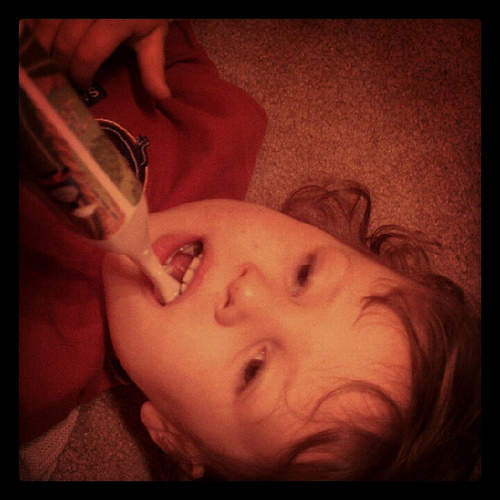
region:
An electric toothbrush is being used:
[20, 49, 182, 309]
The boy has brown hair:
[208, 185, 493, 477]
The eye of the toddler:
[222, 340, 284, 407]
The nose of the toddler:
[211, 259, 267, 330]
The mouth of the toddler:
[123, 230, 220, 311]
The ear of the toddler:
[137, 394, 207, 481]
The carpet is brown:
[260, 54, 472, 211]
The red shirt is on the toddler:
[20, 19, 268, 443]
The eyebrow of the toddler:
[323, 244, 370, 314]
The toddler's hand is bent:
[20, 18, 177, 104]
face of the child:
[98, 195, 447, 479]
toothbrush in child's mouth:
[13, 19, 183, 305]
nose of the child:
[216, 262, 281, 329]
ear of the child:
[140, 400, 206, 477]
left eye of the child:
[229, 338, 276, 398]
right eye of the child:
[288, 244, 326, 297]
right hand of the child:
[25, 17, 177, 99]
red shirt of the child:
[11, 13, 268, 435]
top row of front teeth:
[180, 253, 202, 291]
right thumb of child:
[135, 25, 170, 105]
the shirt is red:
[90, 55, 251, 222]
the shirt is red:
[26, 218, 175, 464]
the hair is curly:
[279, 165, 476, 351]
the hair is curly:
[252, 171, 424, 304]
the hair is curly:
[301, 178, 453, 459]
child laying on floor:
[17, 20, 497, 498]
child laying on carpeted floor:
[1, 2, 491, 497]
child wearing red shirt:
[6, 10, 480, 478]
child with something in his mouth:
[14, 2, 483, 477]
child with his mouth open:
[0, 0, 497, 495]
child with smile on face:
[0, 9, 495, 498]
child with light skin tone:
[5, 5, 495, 499]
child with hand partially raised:
[1, 0, 493, 495]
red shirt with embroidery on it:
[0, 5, 497, 497]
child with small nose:
[2, 54, 492, 493]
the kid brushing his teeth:
[8, 35, 360, 424]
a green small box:
[6, 73, 308, 393]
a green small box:
[43, 118, 250, 350]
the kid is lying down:
[44, 31, 451, 494]